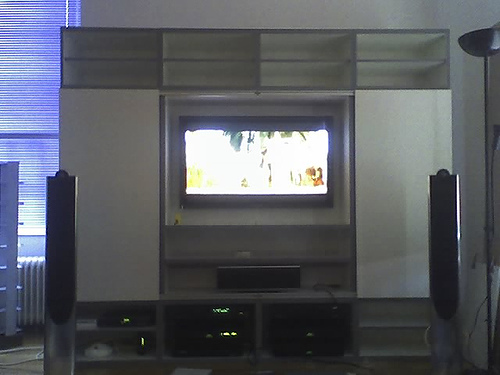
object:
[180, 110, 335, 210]
electronic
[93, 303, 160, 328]
electronic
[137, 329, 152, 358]
electronic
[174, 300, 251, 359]
electronic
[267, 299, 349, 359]
electronic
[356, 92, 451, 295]
wall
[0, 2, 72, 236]
window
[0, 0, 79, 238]
shade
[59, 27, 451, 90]
shelf space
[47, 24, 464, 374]
entertainment center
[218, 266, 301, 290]
speaker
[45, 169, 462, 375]
sound system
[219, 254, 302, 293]
equipment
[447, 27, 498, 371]
lamp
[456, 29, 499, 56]
shade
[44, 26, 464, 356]
center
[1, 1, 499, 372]
living room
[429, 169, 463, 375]
speaker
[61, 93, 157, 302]
wall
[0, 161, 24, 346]
object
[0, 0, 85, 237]
venetian blinds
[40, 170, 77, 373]
speaker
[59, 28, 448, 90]
shelves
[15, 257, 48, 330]
radiator